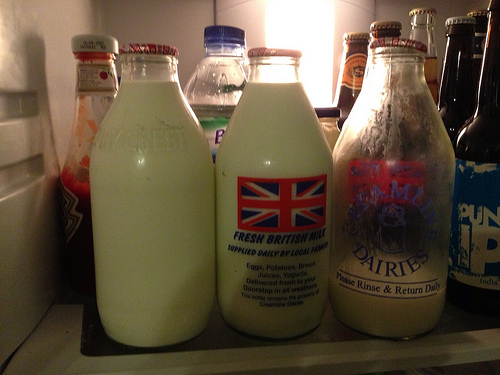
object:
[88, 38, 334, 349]
bottles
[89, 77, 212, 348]
milk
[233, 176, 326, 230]
flag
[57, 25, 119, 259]
ketchup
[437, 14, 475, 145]
bottle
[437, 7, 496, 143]
four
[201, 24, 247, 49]
blue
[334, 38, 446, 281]
empty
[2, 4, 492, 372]
fridge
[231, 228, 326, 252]
text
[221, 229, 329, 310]
logo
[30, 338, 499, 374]
shelf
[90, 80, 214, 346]
liquid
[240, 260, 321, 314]
letters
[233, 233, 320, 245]
britain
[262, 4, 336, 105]
light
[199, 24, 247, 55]
cap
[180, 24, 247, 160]
water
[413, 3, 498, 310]
beer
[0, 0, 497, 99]
background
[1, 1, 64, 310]
refrigerator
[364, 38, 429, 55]
lid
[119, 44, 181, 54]
red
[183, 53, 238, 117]
container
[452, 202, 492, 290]
white